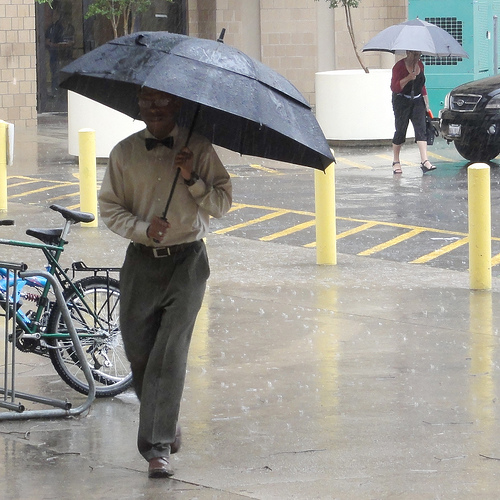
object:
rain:
[210, 254, 420, 465]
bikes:
[1, 199, 150, 398]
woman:
[377, 36, 436, 183]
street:
[0, 133, 500, 272]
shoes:
[141, 453, 180, 480]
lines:
[212, 200, 303, 243]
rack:
[0, 378, 75, 412]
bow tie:
[144, 135, 178, 152]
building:
[1, 1, 500, 142]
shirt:
[90, 120, 234, 250]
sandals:
[419, 157, 438, 175]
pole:
[72, 125, 100, 230]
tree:
[83, 1, 155, 45]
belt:
[129, 236, 207, 260]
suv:
[435, 68, 500, 168]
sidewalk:
[0, 198, 500, 500]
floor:
[0, 147, 500, 500]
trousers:
[111, 243, 215, 463]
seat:
[45, 201, 96, 229]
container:
[65, 85, 149, 158]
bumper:
[440, 121, 467, 143]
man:
[51, 23, 248, 483]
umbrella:
[68, 12, 337, 194]